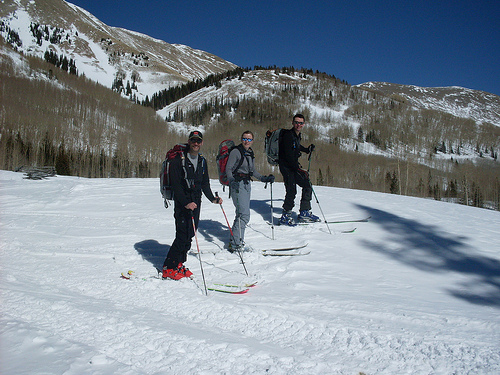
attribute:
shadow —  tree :
[347, 202, 450, 264]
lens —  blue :
[242, 131, 254, 141]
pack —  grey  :
[264, 125, 284, 164]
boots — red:
[152, 240, 194, 285]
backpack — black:
[263, 127, 282, 176]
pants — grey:
[233, 184, 265, 250]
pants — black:
[159, 210, 217, 282]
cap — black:
[167, 117, 214, 157]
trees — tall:
[119, 59, 366, 122]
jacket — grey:
[205, 130, 263, 200]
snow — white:
[293, 271, 423, 370]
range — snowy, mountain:
[0, 0, 495, 219]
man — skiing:
[199, 106, 275, 278]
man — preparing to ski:
[131, 106, 236, 326]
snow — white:
[15, 137, 498, 355]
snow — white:
[37, 145, 498, 363]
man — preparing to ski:
[256, 71, 326, 245]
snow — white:
[18, 194, 450, 371]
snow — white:
[28, 175, 433, 371]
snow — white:
[6, 177, 487, 373]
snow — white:
[23, 153, 487, 373]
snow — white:
[36, 152, 423, 372]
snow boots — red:
[148, 254, 199, 297]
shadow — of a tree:
[360, 190, 498, 291]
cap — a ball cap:
[178, 125, 208, 149]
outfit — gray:
[224, 147, 258, 251]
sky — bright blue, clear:
[104, 0, 494, 70]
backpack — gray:
[246, 110, 289, 180]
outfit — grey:
[207, 150, 262, 245]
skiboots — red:
[143, 257, 201, 289]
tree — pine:
[327, 167, 498, 329]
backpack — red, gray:
[205, 129, 245, 193]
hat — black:
[178, 117, 220, 158]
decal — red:
[170, 125, 214, 155]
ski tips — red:
[227, 259, 276, 309]